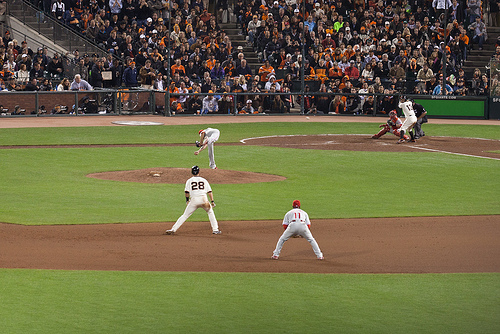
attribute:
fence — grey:
[0, 88, 499, 118]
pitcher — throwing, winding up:
[194, 126, 220, 168]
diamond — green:
[0, 132, 498, 274]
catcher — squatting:
[372, 110, 410, 142]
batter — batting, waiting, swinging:
[397, 96, 416, 142]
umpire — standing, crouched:
[410, 101, 427, 139]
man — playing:
[272, 200, 325, 259]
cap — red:
[291, 200, 301, 207]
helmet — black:
[192, 165, 200, 176]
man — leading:
[166, 165, 221, 235]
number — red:
[294, 211, 301, 220]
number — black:
[190, 180, 205, 191]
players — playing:
[166, 94, 428, 259]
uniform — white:
[170, 175, 221, 230]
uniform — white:
[274, 209, 322, 259]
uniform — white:
[203, 127, 221, 165]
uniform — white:
[400, 100, 417, 138]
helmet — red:
[388, 108, 399, 119]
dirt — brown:
[0, 216, 499, 273]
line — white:
[411, 144, 500, 164]